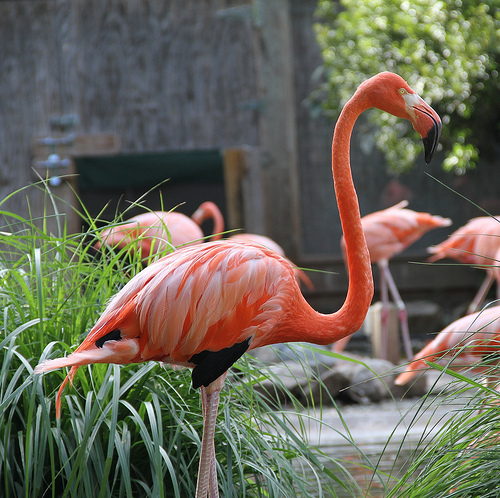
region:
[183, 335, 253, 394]
black feathers on underside of flamingo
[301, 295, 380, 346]
curve of flamingo neck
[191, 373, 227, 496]
long skinny legs of flamingo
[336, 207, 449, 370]
long legs of flamingo in distance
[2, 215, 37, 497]
long green water grass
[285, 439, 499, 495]
grass at edge of the water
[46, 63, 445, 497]
flamingo standing at edge of water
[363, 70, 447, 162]
orange head with black beak of flamingo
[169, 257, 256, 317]
orange and peach colored feathers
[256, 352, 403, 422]
grey boulders near edge of water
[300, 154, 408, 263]
neck of the bird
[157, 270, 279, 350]
feathers on the side of the bird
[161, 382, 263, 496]
legs of the bird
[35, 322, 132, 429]
tail feather of the bird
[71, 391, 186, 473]
green grass next to the bird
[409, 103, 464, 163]
beak of the bird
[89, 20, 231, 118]
wall in the background of the photo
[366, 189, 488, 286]
birds in the background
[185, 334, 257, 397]
black feather on the bird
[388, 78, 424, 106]
eye of the bird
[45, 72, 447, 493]
a bird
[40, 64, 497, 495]
birds in a zoo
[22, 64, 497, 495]
flamingos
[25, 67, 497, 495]
the flamingos are pink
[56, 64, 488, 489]
the birds have long legs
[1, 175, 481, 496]
tall grass is behind the bird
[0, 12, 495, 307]
a building is behind the flamingos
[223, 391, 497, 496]
water is behind the grass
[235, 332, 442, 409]
rocks are in the enclosure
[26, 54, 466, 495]
the bird closest to us has a few black feathers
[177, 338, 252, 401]
Black on the bird.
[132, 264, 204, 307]
The feathers are pale pink.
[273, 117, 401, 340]
The neck is pink.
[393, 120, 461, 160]
Part of the beak is black.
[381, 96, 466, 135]
Part of the beak is pink.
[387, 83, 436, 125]
There is white under the eyes.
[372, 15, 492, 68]
The leaves on the tree are green.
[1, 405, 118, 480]
Leaves behind the bird.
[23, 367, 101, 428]
The tail feathers are pink.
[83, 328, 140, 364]
Black under the wing.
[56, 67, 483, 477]
real flamingo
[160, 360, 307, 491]
legs of real flamingo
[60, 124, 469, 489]
collection of real, pink flamingos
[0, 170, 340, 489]
wide-bladed foilage at zoo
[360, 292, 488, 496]
plant used for decoration at zoo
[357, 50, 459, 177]
head of actual flamingo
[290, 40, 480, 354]
head and neck of real-life flamingo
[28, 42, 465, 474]
zoo scene during the daylight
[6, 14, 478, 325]
zoo house during the daytime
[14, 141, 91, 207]
lighting fixture on zoo building